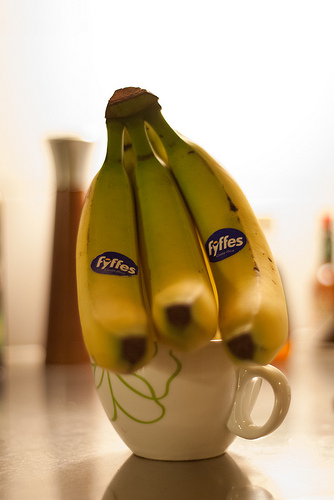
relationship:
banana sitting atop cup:
[75, 112, 154, 372] [88, 338, 289, 460]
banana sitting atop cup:
[131, 124, 216, 346] [88, 338, 289, 460]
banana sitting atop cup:
[145, 98, 288, 365] [88, 338, 289, 460]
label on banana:
[90, 251, 138, 276] [131, 124, 216, 346]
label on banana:
[90, 251, 138, 276] [71, 103, 157, 373]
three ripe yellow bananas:
[78, 108, 232, 265] [64, 104, 299, 377]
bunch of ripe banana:
[76, 221, 288, 372] [178, 146, 294, 357]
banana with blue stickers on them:
[127, 118, 220, 347] [81, 222, 257, 310]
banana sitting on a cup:
[75, 117, 150, 375] [90, 321, 285, 456]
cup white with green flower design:
[88, 338, 289, 460] [89, 338, 181, 422]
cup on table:
[88, 340, 290, 464] [3, 422, 90, 483]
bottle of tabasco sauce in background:
[310, 236, 328, 338] [0, 235, 333, 476]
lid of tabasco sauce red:
[322, 216, 331, 229] [319, 223, 332, 250]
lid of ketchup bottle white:
[47, 135, 93, 187] [52, 134, 86, 182]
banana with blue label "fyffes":
[145, 98, 288, 365] [96, 268, 139, 285]